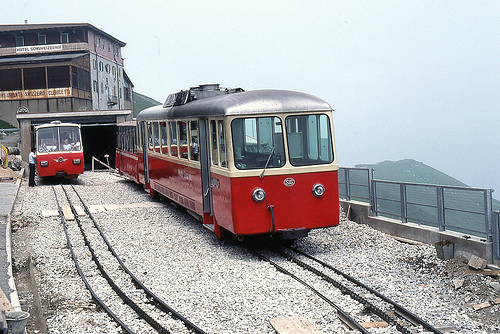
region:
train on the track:
[115, 83, 344, 238]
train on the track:
[30, 118, 88, 176]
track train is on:
[270, 255, 385, 329]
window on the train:
[236, 112, 331, 160]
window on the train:
[41, 130, 78, 151]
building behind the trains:
[8, 17, 125, 127]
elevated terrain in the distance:
[371, 146, 478, 207]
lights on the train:
[241, 181, 333, 206]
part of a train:
[249, 206, 258, 221]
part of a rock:
[275, 248, 280, 260]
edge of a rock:
[226, 262, 237, 277]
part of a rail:
[411, 150, 419, 185]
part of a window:
[270, 143, 286, 173]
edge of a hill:
[363, 133, 378, 156]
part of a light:
[251, 178, 264, 197]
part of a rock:
[156, 272, 168, 287]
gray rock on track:
[232, 290, 266, 307]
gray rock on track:
[158, 250, 190, 271]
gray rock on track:
[139, 239, 171, 259]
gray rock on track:
[183, 230, 224, 253]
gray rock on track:
[118, 235, 148, 245]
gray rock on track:
[109, 212, 141, 242]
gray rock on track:
[152, 222, 207, 244]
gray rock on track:
[89, 181, 106, 193]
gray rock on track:
[357, 243, 387, 270]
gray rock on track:
[316, 247, 348, 272]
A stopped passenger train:
[119, 80, 354, 253]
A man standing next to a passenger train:
[24, 111, 90, 184]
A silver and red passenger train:
[111, 79, 351, 243]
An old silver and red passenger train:
[113, 78, 343, 250]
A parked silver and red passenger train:
[111, 77, 354, 250]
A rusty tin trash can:
[433, 237, 457, 262]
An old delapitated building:
[1, 25, 133, 110]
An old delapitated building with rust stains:
[3, 28, 123, 114]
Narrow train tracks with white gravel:
[54, 209, 186, 310]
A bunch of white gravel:
[111, 202, 171, 249]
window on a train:
[283, 112, 332, 161]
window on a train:
[231, 118, 281, 169]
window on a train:
[218, 120, 230, 167]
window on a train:
[206, 117, 221, 163]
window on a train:
[188, 116, 201, 160]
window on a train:
[175, 119, 187, 164]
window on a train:
[166, 120, 176, 154]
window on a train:
[160, 119, 172, 151]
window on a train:
[58, 125, 80, 149]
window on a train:
[38, 124, 58, 149]